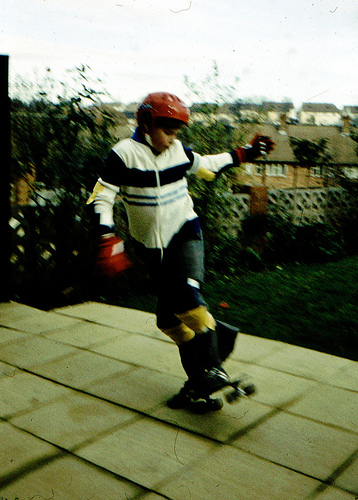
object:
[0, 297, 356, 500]
deck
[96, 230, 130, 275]
right hand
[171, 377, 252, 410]
wheels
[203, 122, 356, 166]
roof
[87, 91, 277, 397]
boy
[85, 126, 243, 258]
sweater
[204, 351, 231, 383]
shoe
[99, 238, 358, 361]
grass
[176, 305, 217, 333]
kneepad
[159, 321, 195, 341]
kneepad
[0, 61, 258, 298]
bush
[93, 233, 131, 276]
glove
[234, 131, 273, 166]
glove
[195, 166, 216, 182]
patch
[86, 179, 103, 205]
patch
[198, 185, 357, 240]
fence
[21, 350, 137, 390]
crack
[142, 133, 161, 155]
strap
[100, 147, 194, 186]
stripe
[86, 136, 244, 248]
sweater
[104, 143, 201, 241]
sweater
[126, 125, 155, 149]
collar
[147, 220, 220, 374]
jeans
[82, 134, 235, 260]
sweatshirt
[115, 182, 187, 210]
stripes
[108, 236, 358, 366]
path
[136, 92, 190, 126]
helmet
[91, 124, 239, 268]
jacket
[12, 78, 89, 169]
tree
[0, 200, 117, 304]
fence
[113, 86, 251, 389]
young boy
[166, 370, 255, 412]
skateboard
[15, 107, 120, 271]
tree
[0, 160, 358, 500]
backyard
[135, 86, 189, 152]
head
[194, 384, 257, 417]
wheels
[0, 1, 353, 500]
air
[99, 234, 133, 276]
hand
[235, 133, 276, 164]
hand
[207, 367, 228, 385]
stripe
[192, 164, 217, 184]
elbow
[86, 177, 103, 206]
elbow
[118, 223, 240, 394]
down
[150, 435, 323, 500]
back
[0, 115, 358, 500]
house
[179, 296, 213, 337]
knee